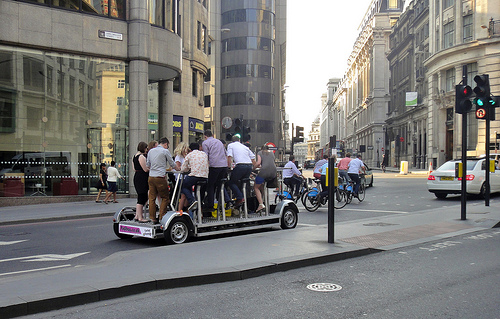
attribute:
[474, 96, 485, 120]
light — black, traffic, red, stop, green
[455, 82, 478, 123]
light — red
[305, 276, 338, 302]
manhole — small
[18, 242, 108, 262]
paint — white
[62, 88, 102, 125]
glass — clear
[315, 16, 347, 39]
sky — bright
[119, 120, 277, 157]
people — standing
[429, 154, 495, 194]
car — white, driving, sedan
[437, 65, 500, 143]
lights — red, black, traffic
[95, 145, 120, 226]
women — walking, talking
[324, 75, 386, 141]
building — glass, cream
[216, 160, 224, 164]
shirt — purple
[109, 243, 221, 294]
passwalk — gray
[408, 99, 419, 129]
sign — hanging, green, white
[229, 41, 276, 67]
window — glass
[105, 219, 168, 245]
license plate — purple, white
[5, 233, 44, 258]
arrow — white